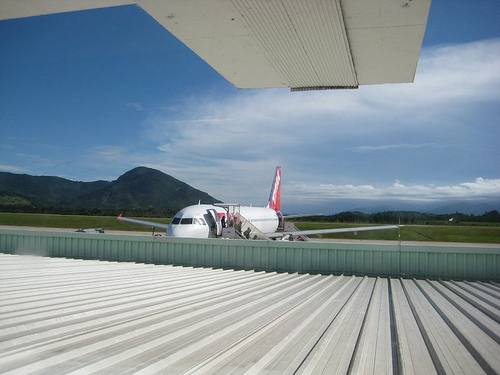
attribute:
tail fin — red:
[107, 164, 421, 253]